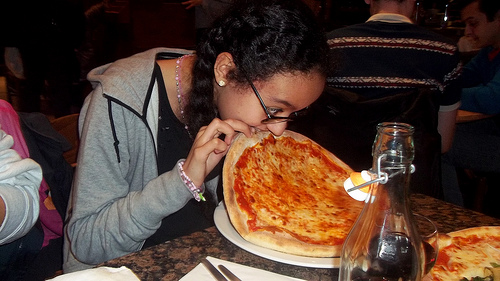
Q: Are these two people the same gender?
A: No, they are both male and female.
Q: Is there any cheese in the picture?
A: Yes, there is cheese.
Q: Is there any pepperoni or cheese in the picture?
A: Yes, there is cheese.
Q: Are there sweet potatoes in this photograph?
A: No, there are no sweet potatoes.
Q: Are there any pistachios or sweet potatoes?
A: No, there are no sweet potatoes or pistachios.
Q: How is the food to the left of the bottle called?
A: The food is cheese.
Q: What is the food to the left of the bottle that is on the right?
A: The food is cheese.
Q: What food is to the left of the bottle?
A: The food is cheese.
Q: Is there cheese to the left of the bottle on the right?
A: Yes, there is cheese to the left of the bottle.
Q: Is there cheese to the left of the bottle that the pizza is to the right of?
A: Yes, there is cheese to the left of the bottle.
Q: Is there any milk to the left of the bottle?
A: No, there is cheese to the left of the bottle.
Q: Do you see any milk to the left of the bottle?
A: No, there is cheese to the left of the bottle.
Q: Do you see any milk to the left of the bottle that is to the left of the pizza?
A: No, there is cheese to the left of the bottle.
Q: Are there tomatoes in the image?
A: Yes, there is a tomato.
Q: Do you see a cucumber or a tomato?
A: Yes, there is a tomato.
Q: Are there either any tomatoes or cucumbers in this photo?
A: Yes, there is a tomato.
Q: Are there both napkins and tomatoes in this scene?
A: Yes, there are both a tomato and a napkin.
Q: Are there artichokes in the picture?
A: No, there are no artichokes.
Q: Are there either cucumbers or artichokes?
A: No, there are no artichokes or cucumbers.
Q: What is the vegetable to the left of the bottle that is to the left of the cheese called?
A: The vegetable is a tomato.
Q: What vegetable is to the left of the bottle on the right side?
A: The vegetable is a tomato.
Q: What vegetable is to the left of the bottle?
A: The vegetable is a tomato.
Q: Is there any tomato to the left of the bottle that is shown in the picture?
A: Yes, there is a tomato to the left of the bottle.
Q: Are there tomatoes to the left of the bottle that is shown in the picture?
A: Yes, there is a tomato to the left of the bottle.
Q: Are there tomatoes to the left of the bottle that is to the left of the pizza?
A: Yes, there is a tomato to the left of the bottle.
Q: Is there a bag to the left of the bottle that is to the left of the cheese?
A: No, there is a tomato to the left of the bottle.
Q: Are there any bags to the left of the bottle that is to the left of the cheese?
A: No, there is a tomato to the left of the bottle.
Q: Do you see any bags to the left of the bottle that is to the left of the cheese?
A: No, there is a tomato to the left of the bottle.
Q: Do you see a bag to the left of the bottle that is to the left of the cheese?
A: No, there is a tomato to the left of the bottle.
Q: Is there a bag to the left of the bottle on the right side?
A: No, there is a tomato to the left of the bottle.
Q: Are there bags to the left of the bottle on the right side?
A: No, there is a tomato to the left of the bottle.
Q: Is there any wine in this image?
A: Yes, there is wine.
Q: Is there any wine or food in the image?
A: Yes, there is wine.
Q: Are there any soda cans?
A: No, there are no soda cans.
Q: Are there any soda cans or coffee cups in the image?
A: No, there are no soda cans or coffee cups.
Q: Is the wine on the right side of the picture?
A: Yes, the wine is on the right of the image.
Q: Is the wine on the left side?
A: No, the wine is on the right of the image.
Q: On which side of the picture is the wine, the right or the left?
A: The wine is on the right of the image.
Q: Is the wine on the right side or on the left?
A: The wine is on the right of the image.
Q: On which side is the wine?
A: The wine is on the right of the image.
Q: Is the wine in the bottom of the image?
A: Yes, the wine is in the bottom of the image.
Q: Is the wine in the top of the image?
A: No, the wine is in the bottom of the image.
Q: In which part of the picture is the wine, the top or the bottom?
A: The wine is in the bottom of the image.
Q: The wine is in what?
A: The wine is in the glass.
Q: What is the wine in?
A: The wine is in the glass.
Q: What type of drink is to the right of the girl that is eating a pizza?
A: The drink is wine.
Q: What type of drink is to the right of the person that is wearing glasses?
A: The drink is wine.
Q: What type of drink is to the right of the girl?
A: The drink is wine.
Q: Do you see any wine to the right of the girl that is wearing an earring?
A: Yes, there is wine to the right of the girl.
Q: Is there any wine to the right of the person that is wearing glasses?
A: Yes, there is wine to the right of the girl.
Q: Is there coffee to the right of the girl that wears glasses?
A: No, there is wine to the right of the girl.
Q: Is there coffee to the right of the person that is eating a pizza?
A: No, there is wine to the right of the girl.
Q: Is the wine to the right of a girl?
A: Yes, the wine is to the right of a girl.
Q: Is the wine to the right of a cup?
A: No, the wine is to the right of a girl.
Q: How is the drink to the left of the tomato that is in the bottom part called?
A: The drink is wine.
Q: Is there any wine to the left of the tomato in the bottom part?
A: Yes, there is wine to the left of the tomato.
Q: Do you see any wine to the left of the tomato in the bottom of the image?
A: Yes, there is wine to the left of the tomato.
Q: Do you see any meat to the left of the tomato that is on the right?
A: No, there is wine to the left of the tomato.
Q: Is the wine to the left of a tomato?
A: Yes, the wine is to the left of a tomato.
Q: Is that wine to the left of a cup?
A: No, the wine is to the left of a tomato.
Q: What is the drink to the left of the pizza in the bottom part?
A: The drink is wine.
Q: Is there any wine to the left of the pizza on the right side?
A: Yes, there is wine to the left of the pizza.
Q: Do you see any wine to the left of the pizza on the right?
A: Yes, there is wine to the left of the pizza.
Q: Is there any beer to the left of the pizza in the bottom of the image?
A: No, there is wine to the left of the pizza.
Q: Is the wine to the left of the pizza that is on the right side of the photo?
A: Yes, the wine is to the left of the pizza.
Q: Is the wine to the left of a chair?
A: No, the wine is to the left of the pizza.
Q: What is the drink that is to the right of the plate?
A: The drink is wine.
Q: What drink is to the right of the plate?
A: The drink is wine.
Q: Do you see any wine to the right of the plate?
A: Yes, there is wine to the right of the plate.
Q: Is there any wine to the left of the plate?
A: No, the wine is to the right of the plate.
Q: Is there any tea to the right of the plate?
A: No, there is wine to the right of the plate.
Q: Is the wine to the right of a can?
A: No, the wine is to the right of the plate.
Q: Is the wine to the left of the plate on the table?
A: No, the wine is to the right of the plate.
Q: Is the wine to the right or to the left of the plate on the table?
A: The wine is to the right of the plate.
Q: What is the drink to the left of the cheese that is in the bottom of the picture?
A: The drink is wine.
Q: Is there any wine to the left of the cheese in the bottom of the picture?
A: Yes, there is wine to the left of the cheese.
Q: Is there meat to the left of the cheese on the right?
A: No, there is wine to the left of the cheese.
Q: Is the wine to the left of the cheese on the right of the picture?
A: Yes, the wine is to the left of the cheese.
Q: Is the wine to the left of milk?
A: No, the wine is to the left of the cheese.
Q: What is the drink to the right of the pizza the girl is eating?
A: The drink is wine.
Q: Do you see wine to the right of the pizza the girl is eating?
A: Yes, there is wine to the right of the pizza.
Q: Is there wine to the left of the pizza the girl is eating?
A: No, the wine is to the right of the pizza.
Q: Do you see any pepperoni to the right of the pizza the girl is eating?
A: No, there is wine to the right of the pizza.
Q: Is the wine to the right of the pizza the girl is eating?
A: Yes, the wine is to the right of the pizza.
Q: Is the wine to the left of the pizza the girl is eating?
A: No, the wine is to the right of the pizza.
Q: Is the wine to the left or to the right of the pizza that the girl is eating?
A: The wine is to the right of the pizza.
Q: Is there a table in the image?
A: Yes, there is a table.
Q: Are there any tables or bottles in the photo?
A: Yes, there is a table.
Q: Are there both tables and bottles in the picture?
A: Yes, there are both a table and a bottle.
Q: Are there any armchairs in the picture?
A: No, there are no armchairs.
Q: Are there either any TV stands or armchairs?
A: No, there are no armchairs or TV stands.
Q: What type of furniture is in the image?
A: The furniture is a table.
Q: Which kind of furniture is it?
A: The piece of furniture is a table.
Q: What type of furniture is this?
A: This is a table.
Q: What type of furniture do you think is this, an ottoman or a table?
A: This is a table.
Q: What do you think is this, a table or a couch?
A: This is a table.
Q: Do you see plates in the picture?
A: Yes, there is a plate.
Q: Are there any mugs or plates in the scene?
A: Yes, there is a plate.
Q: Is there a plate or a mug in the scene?
A: Yes, there is a plate.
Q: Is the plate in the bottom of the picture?
A: Yes, the plate is in the bottom of the image.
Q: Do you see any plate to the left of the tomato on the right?
A: Yes, there is a plate to the left of the tomato.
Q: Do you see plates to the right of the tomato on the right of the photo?
A: No, the plate is to the left of the tomato.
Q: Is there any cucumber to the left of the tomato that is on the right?
A: No, there is a plate to the left of the tomato.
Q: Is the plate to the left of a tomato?
A: Yes, the plate is to the left of a tomato.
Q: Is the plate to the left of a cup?
A: No, the plate is to the left of a tomato.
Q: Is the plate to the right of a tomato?
A: No, the plate is to the left of a tomato.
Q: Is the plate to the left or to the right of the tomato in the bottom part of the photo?
A: The plate is to the left of the tomato.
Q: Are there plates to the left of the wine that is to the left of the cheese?
A: Yes, there is a plate to the left of the wine.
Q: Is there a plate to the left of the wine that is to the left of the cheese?
A: Yes, there is a plate to the left of the wine.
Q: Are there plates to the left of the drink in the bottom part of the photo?
A: Yes, there is a plate to the left of the wine.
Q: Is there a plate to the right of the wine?
A: No, the plate is to the left of the wine.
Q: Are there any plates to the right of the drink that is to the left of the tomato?
A: No, the plate is to the left of the wine.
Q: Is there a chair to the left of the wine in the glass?
A: No, there is a plate to the left of the wine.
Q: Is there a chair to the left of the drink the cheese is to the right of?
A: No, there is a plate to the left of the wine.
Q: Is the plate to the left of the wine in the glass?
A: Yes, the plate is to the left of the wine.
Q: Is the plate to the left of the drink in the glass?
A: Yes, the plate is to the left of the wine.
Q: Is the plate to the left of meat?
A: No, the plate is to the left of the wine.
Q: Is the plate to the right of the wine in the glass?
A: No, the plate is to the left of the wine.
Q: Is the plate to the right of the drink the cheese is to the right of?
A: No, the plate is to the left of the wine.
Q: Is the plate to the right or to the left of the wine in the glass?
A: The plate is to the left of the wine.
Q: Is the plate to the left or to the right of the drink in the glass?
A: The plate is to the left of the wine.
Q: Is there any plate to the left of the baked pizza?
A: Yes, there is a plate to the left of the pizza.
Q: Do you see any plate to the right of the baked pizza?
A: No, the plate is to the left of the pizza.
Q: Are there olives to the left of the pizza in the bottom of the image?
A: No, there is a plate to the left of the pizza.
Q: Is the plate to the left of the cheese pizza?
A: Yes, the plate is to the left of the pizza.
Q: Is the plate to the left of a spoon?
A: No, the plate is to the left of the pizza.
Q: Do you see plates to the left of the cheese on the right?
A: Yes, there is a plate to the left of the cheese.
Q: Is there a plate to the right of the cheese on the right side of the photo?
A: No, the plate is to the left of the cheese.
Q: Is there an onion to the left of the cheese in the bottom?
A: No, there is a plate to the left of the cheese.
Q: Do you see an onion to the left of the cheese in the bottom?
A: No, there is a plate to the left of the cheese.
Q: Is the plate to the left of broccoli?
A: No, the plate is to the left of the cheese.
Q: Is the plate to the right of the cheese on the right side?
A: No, the plate is to the left of the cheese.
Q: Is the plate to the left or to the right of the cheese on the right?
A: The plate is to the left of the cheese.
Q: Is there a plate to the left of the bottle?
A: Yes, there is a plate to the left of the bottle.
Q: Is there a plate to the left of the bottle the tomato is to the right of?
A: Yes, there is a plate to the left of the bottle.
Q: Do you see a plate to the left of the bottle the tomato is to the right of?
A: Yes, there is a plate to the left of the bottle.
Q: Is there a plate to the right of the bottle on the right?
A: No, the plate is to the left of the bottle.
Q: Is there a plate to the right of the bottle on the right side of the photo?
A: No, the plate is to the left of the bottle.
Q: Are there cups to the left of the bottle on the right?
A: No, there is a plate to the left of the bottle.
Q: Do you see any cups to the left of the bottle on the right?
A: No, there is a plate to the left of the bottle.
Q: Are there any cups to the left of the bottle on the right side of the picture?
A: No, there is a plate to the left of the bottle.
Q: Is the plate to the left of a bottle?
A: Yes, the plate is to the left of a bottle.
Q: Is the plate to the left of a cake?
A: No, the plate is to the left of a bottle.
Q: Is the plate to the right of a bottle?
A: No, the plate is to the left of a bottle.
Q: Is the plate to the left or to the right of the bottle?
A: The plate is to the left of the bottle.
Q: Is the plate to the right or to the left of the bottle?
A: The plate is to the left of the bottle.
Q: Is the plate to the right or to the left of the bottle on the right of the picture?
A: The plate is to the left of the bottle.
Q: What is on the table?
A: The plate is on the table.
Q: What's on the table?
A: The plate is on the table.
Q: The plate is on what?
A: The plate is on the table.